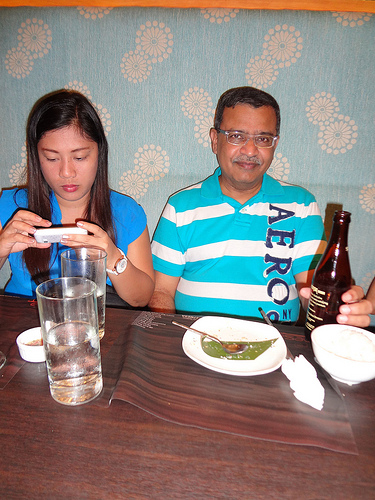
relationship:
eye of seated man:
[255, 133, 271, 146] [154, 79, 371, 325]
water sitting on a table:
[26, 268, 107, 400] [159, 370, 186, 397]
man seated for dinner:
[154, 79, 371, 325] [176, 310, 289, 374]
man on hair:
[154, 79, 371, 325] [213, 73, 283, 126]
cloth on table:
[137, 312, 334, 442] [15, 289, 372, 489]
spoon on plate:
[170, 320, 247, 352] [181, 314, 288, 377]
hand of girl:
[3, 210, 50, 250] [0, 87, 155, 308]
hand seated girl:
[61, 221, 114, 262] [0, 87, 155, 308]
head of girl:
[31, 90, 99, 199] [0, 87, 155, 308]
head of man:
[214, 85, 279, 181] [154, 79, 371, 325]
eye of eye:
[228, 130, 245, 143] [256, 135, 271, 147]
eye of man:
[228, 130, 245, 143] [152, 82, 354, 319]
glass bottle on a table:
[306, 210, 355, 338] [15, 289, 372, 489]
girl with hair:
[2, 80, 113, 255] [23, 91, 116, 281]